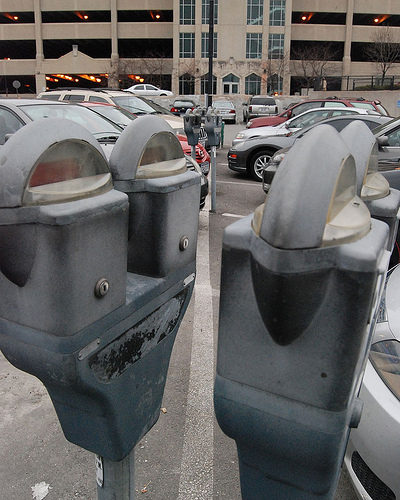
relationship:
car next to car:
[231, 105, 383, 139] [228, 114, 393, 180]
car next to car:
[231, 105, 383, 139] [245, 97, 390, 127]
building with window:
[0, 2, 399, 95] [247, 31, 262, 59]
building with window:
[0, 2, 399, 95] [199, 33, 219, 59]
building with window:
[0, 2, 399, 95] [266, 33, 284, 60]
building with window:
[0, 2, 399, 95] [178, 31, 196, 60]